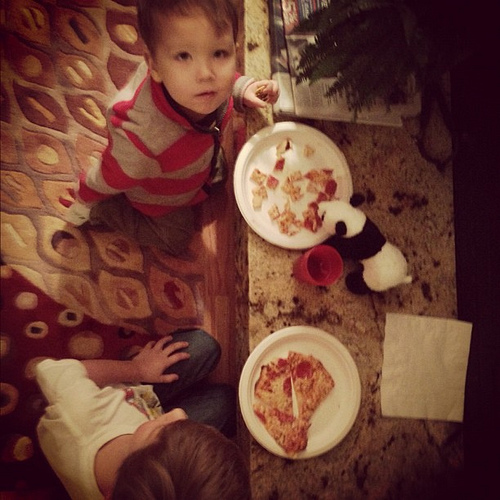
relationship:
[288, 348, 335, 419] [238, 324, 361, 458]
pizza slice in plate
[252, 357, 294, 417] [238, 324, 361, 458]
pizza slice in plate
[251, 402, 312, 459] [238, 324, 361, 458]
pizza slice in plate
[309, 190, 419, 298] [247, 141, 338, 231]
panda plushie eating pizza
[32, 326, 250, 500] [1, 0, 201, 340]
boy on carpet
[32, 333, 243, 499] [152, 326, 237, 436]
boy in jeans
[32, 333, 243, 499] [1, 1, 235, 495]
boy in floor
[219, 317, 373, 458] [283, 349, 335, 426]
plate with pizza slice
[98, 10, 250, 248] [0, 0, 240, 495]
boy on carpet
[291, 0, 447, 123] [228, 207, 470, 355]
plant on table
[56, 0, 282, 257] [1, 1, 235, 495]
boy are sitting on floor